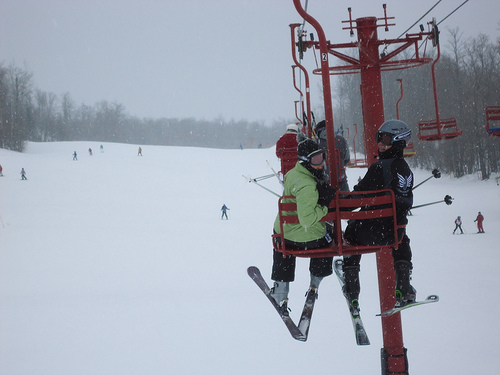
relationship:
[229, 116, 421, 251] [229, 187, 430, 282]
people on lift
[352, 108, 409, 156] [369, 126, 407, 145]
pair of goggles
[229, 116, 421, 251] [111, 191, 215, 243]
people on snow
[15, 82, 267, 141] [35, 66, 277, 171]
trees in distance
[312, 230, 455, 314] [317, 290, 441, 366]
boots and skis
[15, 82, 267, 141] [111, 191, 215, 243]
trees and snow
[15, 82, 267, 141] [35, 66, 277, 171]
trees in background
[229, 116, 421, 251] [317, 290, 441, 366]
people have skis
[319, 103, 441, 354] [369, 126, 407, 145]
man has goggles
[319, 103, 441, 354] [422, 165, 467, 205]
man holding poles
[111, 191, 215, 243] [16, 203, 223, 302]
snow covered ground